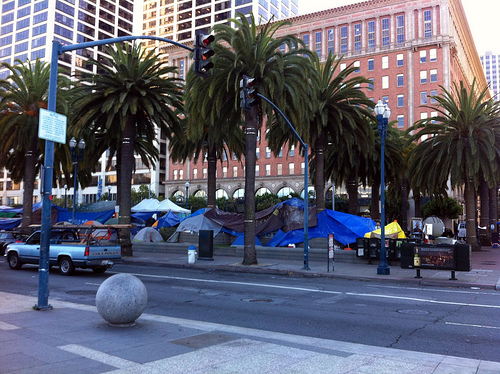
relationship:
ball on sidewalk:
[88, 260, 162, 333] [2, 286, 484, 373]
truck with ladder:
[4, 227, 121, 273] [25, 222, 137, 230]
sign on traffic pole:
[37, 106, 67, 144] [36, 30, 214, 307]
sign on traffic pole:
[37, 106, 67, 144] [240, 77, 310, 271]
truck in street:
[4, 227, 121, 273] [1, 260, 497, 358]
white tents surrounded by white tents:
[156, 199, 188, 211] [126, 197, 158, 210]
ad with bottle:
[405, 241, 464, 270] [407, 246, 424, 268]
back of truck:
[85, 244, 120, 259] [5, 223, 122, 274]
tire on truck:
[60, 255, 68, 275] [6, 228, 120, 269]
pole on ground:
[264, 132, 328, 283] [1, 229, 496, 372]